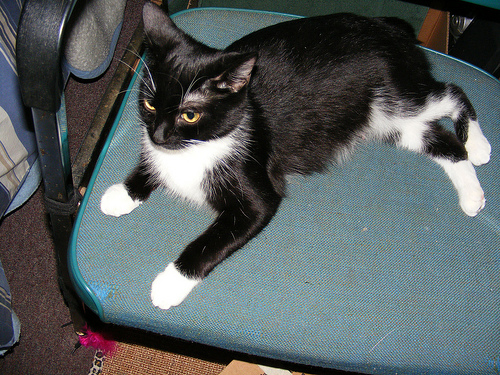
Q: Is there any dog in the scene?
A: No, there are no dogs.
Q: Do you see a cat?
A: Yes, there is a cat.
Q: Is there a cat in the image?
A: Yes, there is a cat.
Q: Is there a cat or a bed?
A: Yes, there is a cat.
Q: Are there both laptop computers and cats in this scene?
A: No, there is a cat but no laptops.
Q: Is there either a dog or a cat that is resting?
A: Yes, the cat is resting.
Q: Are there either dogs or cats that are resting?
A: Yes, the cat is resting.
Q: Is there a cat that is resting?
A: Yes, there is a cat that is resting.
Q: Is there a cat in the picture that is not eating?
A: Yes, there is a cat that is resting.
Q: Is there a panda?
A: No, there are no pandas.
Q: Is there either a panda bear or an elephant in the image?
A: No, there are no pandas or elephants.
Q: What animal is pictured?
A: The animal is a cat.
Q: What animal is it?
A: The animal is a cat.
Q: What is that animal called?
A: This is a cat.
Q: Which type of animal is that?
A: This is a cat.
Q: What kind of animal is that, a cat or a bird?
A: This is a cat.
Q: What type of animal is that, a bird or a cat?
A: This is a cat.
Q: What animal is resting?
A: The animal is a cat.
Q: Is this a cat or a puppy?
A: This is a cat.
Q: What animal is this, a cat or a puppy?
A: This is a cat.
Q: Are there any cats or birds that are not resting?
A: No, there is a cat but it is resting.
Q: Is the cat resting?
A: Yes, the cat is resting.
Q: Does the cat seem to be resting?
A: Yes, the cat is resting.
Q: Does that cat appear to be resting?
A: Yes, the cat is resting.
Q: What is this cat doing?
A: The cat is resting.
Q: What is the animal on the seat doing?
A: The cat is resting.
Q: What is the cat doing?
A: The cat is resting.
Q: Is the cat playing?
A: No, the cat is resting.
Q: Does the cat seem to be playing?
A: No, the cat is resting.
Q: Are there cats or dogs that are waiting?
A: No, there is a cat but it is resting.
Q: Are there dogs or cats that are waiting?
A: No, there is a cat but it is resting.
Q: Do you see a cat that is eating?
A: No, there is a cat but it is resting.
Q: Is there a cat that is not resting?
A: No, there is a cat but it is resting.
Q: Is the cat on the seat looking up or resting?
A: The cat is resting.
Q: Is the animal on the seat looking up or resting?
A: The cat is resting.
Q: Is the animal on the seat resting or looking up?
A: The cat is resting.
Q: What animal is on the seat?
A: The cat is on the seat.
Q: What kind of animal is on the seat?
A: The animal is a cat.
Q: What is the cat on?
A: The cat is on the seat.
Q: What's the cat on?
A: The cat is on the seat.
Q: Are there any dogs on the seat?
A: No, there is a cat on the seat.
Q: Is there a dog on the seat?
A: No, there is a cat on the seat.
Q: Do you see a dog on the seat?
A: No, there is a cat on the seat.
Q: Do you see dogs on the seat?
A: No, there is a cat on the seat.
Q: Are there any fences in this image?
A: No, there are no fences.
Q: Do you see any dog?
A: No, there are no dogs.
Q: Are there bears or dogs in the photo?
A: No, there are no dogs or bears.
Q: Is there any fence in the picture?
A: No, there are no fences.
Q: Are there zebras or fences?
A: No, there are no fences or zebras.